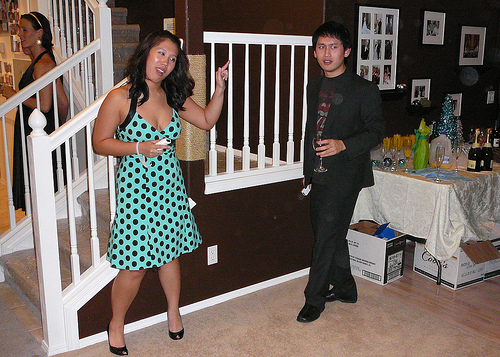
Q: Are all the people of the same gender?
A: No, they are both male and female.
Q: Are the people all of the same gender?
A: No, they are both male and female.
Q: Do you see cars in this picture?
A: No, there are no cars.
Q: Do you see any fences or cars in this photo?
A: No, there are no cars or fences.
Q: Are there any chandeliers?
A: No, there are no chandeliers.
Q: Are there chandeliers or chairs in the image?
A: No, there are no chandeliers or chairs.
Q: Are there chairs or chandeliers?
A: No, there are no chandeliers or chairs.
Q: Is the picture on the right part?
A: Yes, the picture is on the right of the image.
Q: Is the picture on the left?
A: No, the picture is on the right of the image.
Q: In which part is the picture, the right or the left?
A: The picture is on the right of the image.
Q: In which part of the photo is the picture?
A: The picture is on the right of the image.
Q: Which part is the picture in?
A: The picture is on the right of the image.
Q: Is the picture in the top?
A: Yes, the picture is in the top of the image.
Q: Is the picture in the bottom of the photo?
A: No, the picture is in the top of the image.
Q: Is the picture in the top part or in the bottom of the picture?
A: The picture is in the top of the image.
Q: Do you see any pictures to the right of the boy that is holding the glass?
A: Yes, there is a picture to the right of the boy.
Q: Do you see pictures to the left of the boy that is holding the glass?
A: No, the picture is to the right of the boy.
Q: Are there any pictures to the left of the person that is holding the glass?
A: No, the picture is to the right of the boy.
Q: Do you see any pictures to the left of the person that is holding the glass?
A: No, the picture is to the right of the boy.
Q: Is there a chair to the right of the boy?
A: No, there is a picture to the right of the boy.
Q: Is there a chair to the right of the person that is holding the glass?
A: No, there is a picture to the right of the boy.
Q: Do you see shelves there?
A: No, there are no shelves.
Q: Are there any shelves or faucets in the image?
A: No, there are no shelves or faucets.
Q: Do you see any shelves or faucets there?
A: No, there are no shelves or faucets.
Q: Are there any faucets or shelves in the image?
A: No, there are no shelves or faucets.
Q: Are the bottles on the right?
A: Yes, the bottles are on the right of the image.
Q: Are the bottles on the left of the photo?
A: No, the bottles are on the right of the image.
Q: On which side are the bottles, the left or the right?
A: The bottles are on the right of the image.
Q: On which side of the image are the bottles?
A: The bottles are on the right of the image.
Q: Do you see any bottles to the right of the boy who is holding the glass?
A: Yes, there are bottles to the right of the boy.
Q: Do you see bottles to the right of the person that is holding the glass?
A: Yes, there are bottles to the right of the boy.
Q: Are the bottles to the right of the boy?
A: Yes, the bottles are to the right of the boy.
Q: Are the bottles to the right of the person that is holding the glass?
A: Yes, the bottles are to the right of the boy.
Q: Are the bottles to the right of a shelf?
A: No, the bottles are to the right of the boy.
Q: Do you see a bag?
A: No, there are no bags.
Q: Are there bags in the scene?
A: No, there are no bags.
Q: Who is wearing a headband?
A: The girl is wearing a headband.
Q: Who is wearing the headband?
A: The girl is wearing a headband.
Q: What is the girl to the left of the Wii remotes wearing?
A: The girl is wearing a hair band.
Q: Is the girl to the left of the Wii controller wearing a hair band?
A: Yes, the girl is wearing a hair band.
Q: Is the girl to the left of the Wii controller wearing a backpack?
A: No, the girl is wearing a hair band.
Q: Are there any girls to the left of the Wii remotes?
A: Yes, there is a girl to the left of the Wii remotes.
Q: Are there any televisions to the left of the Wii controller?
A: No, there is a girl to the left of the Wii controller.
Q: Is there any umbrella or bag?
A: No, there are no bags or umbrellas.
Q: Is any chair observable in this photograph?
A: No, there are no chairs.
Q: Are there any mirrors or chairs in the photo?
A: No, there are no chairs or mirrors.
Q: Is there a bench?
A: No, there are no benches.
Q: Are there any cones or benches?
A: No, there are no benches or cones.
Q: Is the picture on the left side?
A: No, the picture is on the right of the image.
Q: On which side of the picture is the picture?
A: The picture is on the right of the image.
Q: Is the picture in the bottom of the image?
A: No, the picture is in the top of the image.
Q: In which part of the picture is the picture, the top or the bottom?
A: The picture is in the top of the image.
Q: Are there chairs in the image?
A: No, there are no chairs.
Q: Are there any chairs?
A: No, there are no chairs.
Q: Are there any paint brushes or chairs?
A: No, there are no chairs or paint brushes.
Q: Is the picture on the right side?
A: Yes, the picture is on the right of the image.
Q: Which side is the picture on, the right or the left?
A: The picture is on the right of the image.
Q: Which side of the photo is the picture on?
A: The picture is on the right of the image.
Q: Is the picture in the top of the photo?
A: Yes, the picture is in the top of the image.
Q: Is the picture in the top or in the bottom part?
A: The picture is in the top of the image.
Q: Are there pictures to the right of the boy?
A: Yes, there is a picture to the right of the boy.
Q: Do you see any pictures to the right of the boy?
A: Yes, there is a picture to the right of the boy.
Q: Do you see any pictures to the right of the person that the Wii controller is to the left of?
A: Yes, there is a picture to the right of the boy.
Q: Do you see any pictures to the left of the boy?
A: No, the picture is to the right of the boy.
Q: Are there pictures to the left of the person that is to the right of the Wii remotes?
A: No, the picture is to the right of the boy.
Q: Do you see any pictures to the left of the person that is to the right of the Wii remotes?
A: No, the picture is to the right of the boy.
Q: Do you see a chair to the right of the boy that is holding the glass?
A: No, there is a picture to the right of the boy.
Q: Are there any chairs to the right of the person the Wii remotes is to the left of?
A: No, there is a picture to the right of the boy.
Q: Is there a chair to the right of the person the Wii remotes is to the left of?
A: No, there is a picture to the right of the boy.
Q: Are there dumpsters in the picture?
A: No, there are no dumpsters.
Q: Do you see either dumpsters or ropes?
A: No, there are no dumpsters or ropes.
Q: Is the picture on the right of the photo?
A: Yes, the picture is on the right of the image.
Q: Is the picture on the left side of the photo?
A: No, the picture is on the right of the image.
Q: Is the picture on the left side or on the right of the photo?
A: The picture is on the right of the image.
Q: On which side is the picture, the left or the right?
A: The picture is on the right of the image.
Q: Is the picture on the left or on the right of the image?
A: The picture is on the right of the image.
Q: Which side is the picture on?
A: The picture is on the right of the image.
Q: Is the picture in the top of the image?
A: Yes, the picture is in the top of the image.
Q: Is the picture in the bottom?
A: No, the picture is in the top of the image.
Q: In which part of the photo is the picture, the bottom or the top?
A: The picture is in the top of the image.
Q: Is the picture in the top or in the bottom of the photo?
A: The picture is in the top of the image.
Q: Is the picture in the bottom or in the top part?
A: The picture is in the top of the image.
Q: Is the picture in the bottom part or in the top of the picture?
A: The picture is in the top of the image.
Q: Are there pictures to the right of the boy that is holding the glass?
A: Yes, there is a picture to the right of the boy.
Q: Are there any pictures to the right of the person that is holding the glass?
A: Yes, there is a picture to the right of the boy.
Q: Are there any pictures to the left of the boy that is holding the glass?
A: No, the picture is to the right of the boy.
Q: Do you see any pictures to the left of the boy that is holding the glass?
A: No, the picture is to the right of the boy.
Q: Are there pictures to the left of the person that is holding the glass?
A: No, the picture is to the right of the boy.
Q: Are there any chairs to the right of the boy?
A: No, there is a picture to the right of the boy.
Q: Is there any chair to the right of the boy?
A: No, there is a picture to the right of the boy.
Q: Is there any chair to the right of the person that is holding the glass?
A: No, there is a picture to the right of the boy.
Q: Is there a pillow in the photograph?
A: No, there are no pillows.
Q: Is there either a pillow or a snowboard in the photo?
A: No, there are no pillows or snowboards.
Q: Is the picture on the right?
A: Yes, the picture is on the right of the image.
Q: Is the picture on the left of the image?
A: No, the picture is on the right of the image.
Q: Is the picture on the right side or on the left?
A: The picture is on the right of the image.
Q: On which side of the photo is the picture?
A: The picture is on the right of the image.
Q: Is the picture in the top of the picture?
A: Yes, the picture is in the top of the image.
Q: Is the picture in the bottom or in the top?
A: The picture is in the top of the image.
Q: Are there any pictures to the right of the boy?
A: Yes, there is a picture to the right of the boy.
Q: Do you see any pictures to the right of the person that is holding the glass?
A: Yes, there is a picture to the right of the boy.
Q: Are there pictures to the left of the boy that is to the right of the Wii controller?
A: No, the picture is to the right of the boy.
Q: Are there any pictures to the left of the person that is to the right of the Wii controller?
A: No, the picture is to the right of the boy.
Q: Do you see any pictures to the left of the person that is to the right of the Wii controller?
A: No, the picture is to the right of the boy.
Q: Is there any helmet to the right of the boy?
A: No, there is a picture to the right of the boy.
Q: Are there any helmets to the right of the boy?
A: No, there is a picture to the right of the boy.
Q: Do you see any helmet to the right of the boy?
A: No, there is a picture to the right of the boy.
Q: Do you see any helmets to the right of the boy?
A: No, there is a picture to the right of the boy.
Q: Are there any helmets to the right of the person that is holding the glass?
A: No, there is a picture to the right of the boy.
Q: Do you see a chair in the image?
A: No, there are no chairs.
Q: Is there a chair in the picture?
A: No, there are no chairs.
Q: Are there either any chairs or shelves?
A: No, there are no chairs or shelves.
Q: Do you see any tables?
A: Yes, there is a table.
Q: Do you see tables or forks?
A: Yes, there is a table.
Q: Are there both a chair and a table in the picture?
A: No, there is a table but no chairs.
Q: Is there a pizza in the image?
A: No, there are no pizzas.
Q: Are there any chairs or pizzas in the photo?
A: No, there are no pizzas or chairs.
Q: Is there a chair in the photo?
A: No, there are no chairs.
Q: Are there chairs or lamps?
A: No, there are no chairs or lamps.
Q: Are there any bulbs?
A: No, there are no bulbs.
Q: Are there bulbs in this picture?
A: No, there are no bulbs.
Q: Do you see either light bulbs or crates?
A: No, there are no light bulbs or crates.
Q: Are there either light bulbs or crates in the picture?
A: No, there are no light bulbs or crates.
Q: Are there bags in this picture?
A: No, there are no bags.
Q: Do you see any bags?
A: No, there are no bags.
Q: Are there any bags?
A: No, there are no bags.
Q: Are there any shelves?
A: No, there are no shelves.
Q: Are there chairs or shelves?
A: No, there are no shelves or chairs.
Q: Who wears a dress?
A: The girl wears a dress.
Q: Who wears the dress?
A: The girl wears a dress.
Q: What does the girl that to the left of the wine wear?
A: The girl wears a dress.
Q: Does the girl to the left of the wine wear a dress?
A: Yes, the girl wears a dress.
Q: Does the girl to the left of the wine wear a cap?
A: No, the girl wears a dress.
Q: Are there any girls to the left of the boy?
A: Yes, there is a girl to the left of the boy.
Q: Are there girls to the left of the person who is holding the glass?
A: Yes, there is a girl to the left of the boy.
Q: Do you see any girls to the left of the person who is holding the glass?
A: Yes, there is a girl to the left of the boy.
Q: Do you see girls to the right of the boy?
A: No, the girl is to the left of the boy.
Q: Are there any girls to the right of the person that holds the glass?
A: No, the girl is to the left of the boy.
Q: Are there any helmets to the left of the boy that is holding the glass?
A: No, there is a girl to the left of the boy.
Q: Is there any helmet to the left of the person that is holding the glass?
A: No, there is a girl to the left of the boy.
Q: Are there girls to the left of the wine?
A: Yes, there is a girl to the left of the wine.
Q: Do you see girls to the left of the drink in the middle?
A: Yes, there is a girl to the left of the wine.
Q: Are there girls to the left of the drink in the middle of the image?
A: Yes, there is a girl to the left of the wine.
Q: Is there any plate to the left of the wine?
A: No, there is a girl to the left of the wine.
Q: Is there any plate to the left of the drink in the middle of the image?
A: No, there is a girl to the left of the wine.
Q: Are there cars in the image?
A: No, there are no cars.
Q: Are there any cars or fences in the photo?
A: No, there are no cars or fences.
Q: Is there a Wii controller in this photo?
A: Yes, there is a Wii controller.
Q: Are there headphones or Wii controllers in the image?
A: Yes, there is a Wii controller.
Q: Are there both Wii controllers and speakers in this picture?
A: No, there is a Wii controller but no speakers.